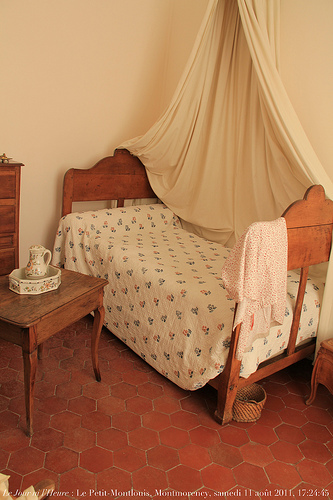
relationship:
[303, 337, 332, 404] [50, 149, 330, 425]
side table for bed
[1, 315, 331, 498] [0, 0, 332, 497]
floor of bedroom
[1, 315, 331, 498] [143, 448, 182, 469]
floor has shapes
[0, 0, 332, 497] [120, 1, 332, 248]
bedroom has curtains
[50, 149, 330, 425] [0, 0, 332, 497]
bed in bedroom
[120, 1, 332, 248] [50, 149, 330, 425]
curtains over bed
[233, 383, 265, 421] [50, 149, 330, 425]
basket under bed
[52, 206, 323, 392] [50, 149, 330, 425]
bedding covers bed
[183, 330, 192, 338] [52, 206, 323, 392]
flower on bedding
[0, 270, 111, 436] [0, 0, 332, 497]
table in bedroom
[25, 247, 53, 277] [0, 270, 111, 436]
pitcher on table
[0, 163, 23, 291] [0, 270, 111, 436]
dresser behind table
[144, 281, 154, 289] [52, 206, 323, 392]
flower on bedding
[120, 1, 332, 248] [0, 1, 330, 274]
curtains on wall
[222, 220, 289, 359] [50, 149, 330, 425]
blanket hanging off bed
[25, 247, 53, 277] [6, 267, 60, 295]
pitcher and bowl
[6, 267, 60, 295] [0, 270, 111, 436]
bowl on table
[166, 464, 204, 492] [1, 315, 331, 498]
tile on floor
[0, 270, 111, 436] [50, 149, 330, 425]
table next to bed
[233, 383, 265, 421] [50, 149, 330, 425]
basket underneath bed